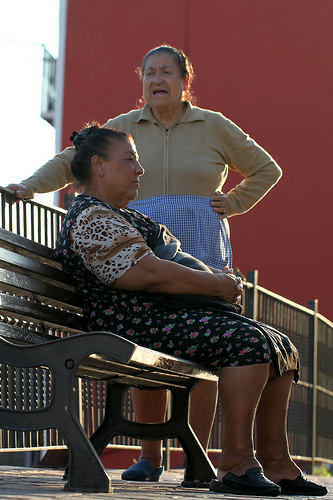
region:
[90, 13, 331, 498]
two old women at a bus stop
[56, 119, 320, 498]
a hefty women sitting on a bench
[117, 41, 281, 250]
an old woman wearing an apron in public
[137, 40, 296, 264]
an old woman yelling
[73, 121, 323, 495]
an old woman sitting quietly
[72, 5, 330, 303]
a woman standing next to the bench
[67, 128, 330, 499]
a woman waiting for her bus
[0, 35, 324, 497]
two women at a bus stop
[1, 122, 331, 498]
a woman sitting on an iron and wooden bench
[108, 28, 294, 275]
an old woman with her hand at her hip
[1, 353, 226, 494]
Legs of black bench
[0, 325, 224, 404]
Seat of black bench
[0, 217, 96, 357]
Back of black bench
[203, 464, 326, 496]
Black shoes woman is wearing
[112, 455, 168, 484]
Dark colored shoe woman is wearing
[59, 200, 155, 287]
Leopard spotted undershirt woman is wearing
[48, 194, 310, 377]
Flowered black dress woman is wearing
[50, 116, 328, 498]
Woman sitting on bench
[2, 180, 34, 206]
Woman's hand on railing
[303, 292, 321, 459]
Metal fence post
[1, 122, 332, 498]
a lady is sitting on a bench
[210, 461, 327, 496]
the lady has slippers on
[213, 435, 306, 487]
the ankles are swollen on the woman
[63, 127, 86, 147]
a hair clip is in the woman's hair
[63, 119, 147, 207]
the lady has her hair up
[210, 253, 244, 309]
the woman's hands are folded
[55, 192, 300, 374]
a flowered jumper is on the girl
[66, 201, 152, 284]
a leopard print blouse is on the lady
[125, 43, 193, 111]
the woman has her mouth open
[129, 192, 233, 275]
a checkered apron is on the woman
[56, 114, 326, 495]
Older lady sitting on bench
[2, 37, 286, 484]
Older woman in apron standing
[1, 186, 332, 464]
Black, metal fence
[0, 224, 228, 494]
Metal and wood bench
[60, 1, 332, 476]
Red wall behind women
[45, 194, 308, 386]
Black dress with flower pattern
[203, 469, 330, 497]
Black slip-on shoes on feet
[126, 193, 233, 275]
Blue and white checked apron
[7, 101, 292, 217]
Cream colored collared zip-up top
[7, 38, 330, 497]
Two women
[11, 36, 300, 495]
Two women near each other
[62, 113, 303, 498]
a woman sitting on a bench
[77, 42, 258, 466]
a woman standing near a bench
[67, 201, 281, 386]
A black dress on a woman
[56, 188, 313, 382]
A black dress with flowers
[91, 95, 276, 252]
A brown dress with a blue apron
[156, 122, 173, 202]
A zipper on the front of a dress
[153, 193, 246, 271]
A blue and white checkered apron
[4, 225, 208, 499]
A black bench near a fence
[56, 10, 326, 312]
A red building behind two women